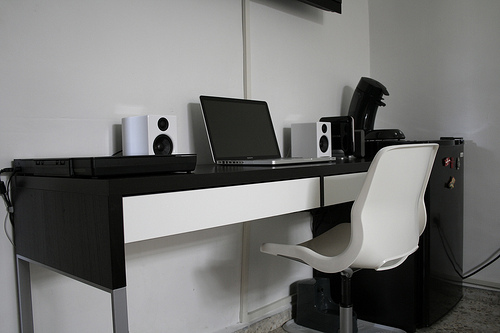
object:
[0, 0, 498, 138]
wall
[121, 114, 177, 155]
stereo speaker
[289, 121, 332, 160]
stereo speaker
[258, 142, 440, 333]
stool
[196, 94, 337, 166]
laptop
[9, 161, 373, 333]
desk